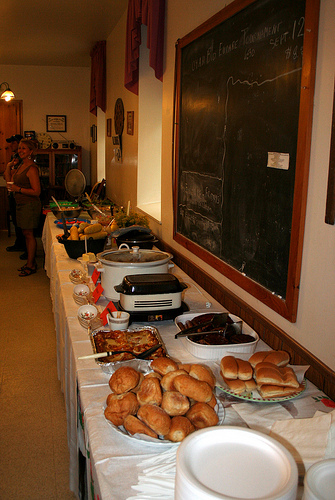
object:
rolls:
[173, 374, 211, 403]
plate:
[102, 397, 226, 446]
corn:
[70, 226, 79, 241]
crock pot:
[94, 243, 175, 303]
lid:
[102, 247, 170, 265]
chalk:
[241, 272, 246, 276]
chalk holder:
[174, 232, 288, 303]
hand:
[8, 182, 20, 193]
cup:
[7, 182, 14, 192]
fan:
[65, 170, 85, 196]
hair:
[17, 136, 33, 151]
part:
[227, 105, 242, 126]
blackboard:
[172, 2, 321, 298]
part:
[183, 381, 199, 392]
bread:
[175, 373, 212, 402]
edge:
[218, 386, 307, 404]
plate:
[215, 365, 307, 402]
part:
[101, 439, 113, 451]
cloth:
[40, 219, 335, 498]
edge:
[169, 32, 183, 244]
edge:
[174, 230, 283, 305]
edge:
[289, 1, 320, 322]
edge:
[176, 1, 255, 49]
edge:
[40, 208, 104, 500]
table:
[47, 214, 335, 500]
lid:
[113, 272, 190, 295]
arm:
[6, 165, 41, 199]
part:
[24, 382, 46, 405]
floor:
[2, 233, 70, 499]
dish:
[105, 355, 226, 444]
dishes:
[171, 425, 300, 500]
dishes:
[301, 458, 335, 499]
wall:
[162, 0, 335, 372]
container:
[174, 310, 260, 359]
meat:
[229, 333, 255, 344]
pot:
[93, 240, 171, 275]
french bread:
[85, 223, 102, 233]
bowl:
[56, 232, 107, 259]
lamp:
[0, 79, 15, 104]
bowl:
[48, 204, 83, 219]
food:
[55, 207, 80, 211]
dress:
[12, 162, 44, 233]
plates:
[171, 423, 298, 498]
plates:
[302, 455, 334, 500]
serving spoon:
[78, 344, 162, 361]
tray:
[85, 325, 173, 375]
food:
[93, 330, 163, 360]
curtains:
[125, 0, 141, 94]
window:
[137, 19, 162, 218]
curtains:
[91, 39, 106, 115]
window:
[94, 106, 104, 180]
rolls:
[221, 353, 238, 382]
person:
[7, 136, 42, 279]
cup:
[107, 311, 131, 331]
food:
[116, 312, 121, 318]